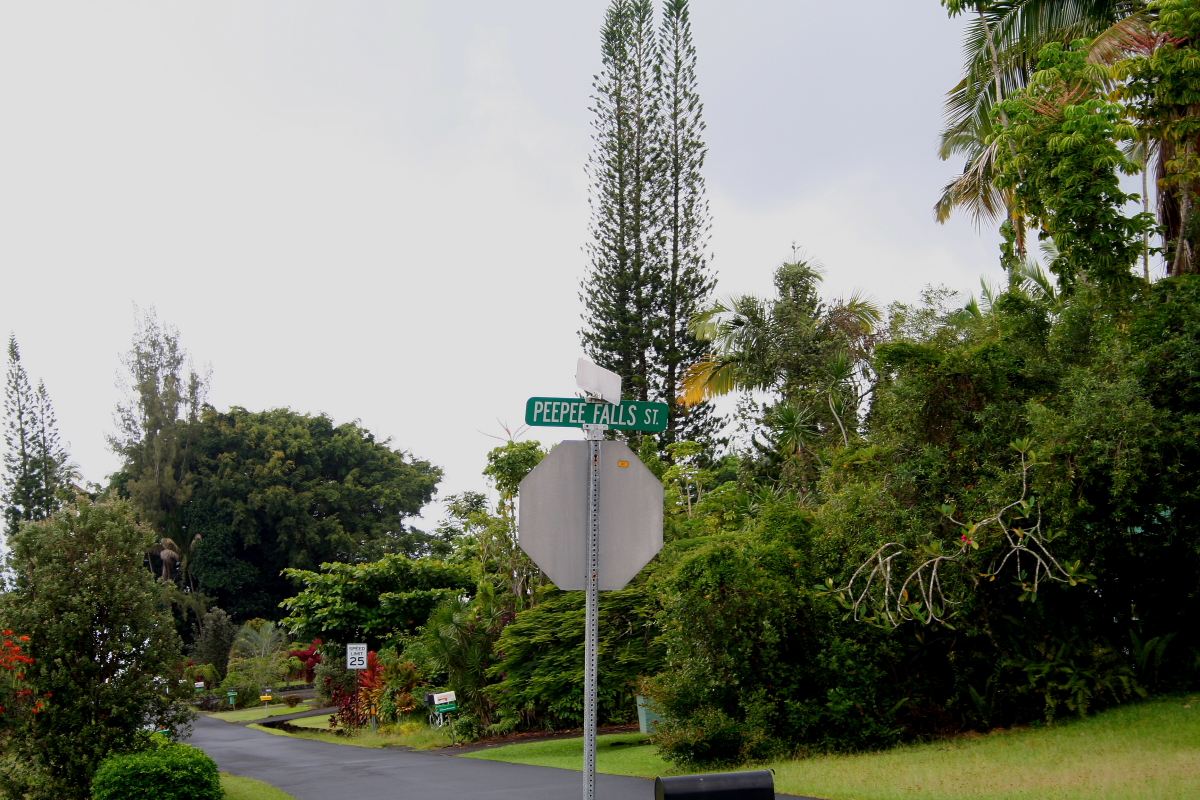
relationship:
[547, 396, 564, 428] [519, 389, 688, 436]
letter on sign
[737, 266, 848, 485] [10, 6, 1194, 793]
tree in woods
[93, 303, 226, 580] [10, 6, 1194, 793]
tree in woods